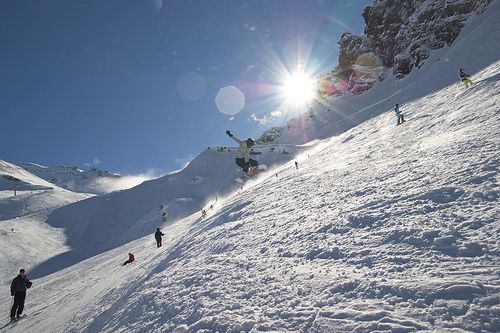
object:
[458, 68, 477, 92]
person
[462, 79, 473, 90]
pants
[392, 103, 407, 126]
person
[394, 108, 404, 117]
coat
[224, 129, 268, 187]
person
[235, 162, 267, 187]
snowboard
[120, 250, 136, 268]
person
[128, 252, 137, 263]
jacket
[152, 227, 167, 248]
person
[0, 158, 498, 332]
snow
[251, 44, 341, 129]
sun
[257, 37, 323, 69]
flares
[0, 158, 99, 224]
hill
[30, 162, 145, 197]
hill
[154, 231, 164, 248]
clothing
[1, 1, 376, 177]
sky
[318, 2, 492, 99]
trees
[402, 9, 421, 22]
snow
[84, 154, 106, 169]
clouds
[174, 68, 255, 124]
glare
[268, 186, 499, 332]
tracks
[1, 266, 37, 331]
skier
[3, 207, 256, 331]
slope